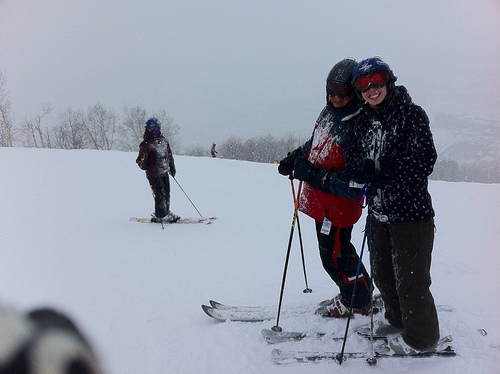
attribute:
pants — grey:
[363, 217, 440, 349]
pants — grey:
[314, 217, 374, 308]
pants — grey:
[147, 174, 171, 215]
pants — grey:
[210, 152, 216, 158]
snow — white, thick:
[0, 143, 492, 368]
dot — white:
[394, 205, 408, 225]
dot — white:
[356, 110, 378, 127]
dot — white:
[409, 208, 414, 213]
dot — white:
[407, 171, 422, 182]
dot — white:
[387, 134, 396, 140]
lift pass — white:
[315, 212, 336, 240]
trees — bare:
[2, 82, 498, 191]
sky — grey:
[167, 0, 376, 120]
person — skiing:
[132, 118, 185, 223]